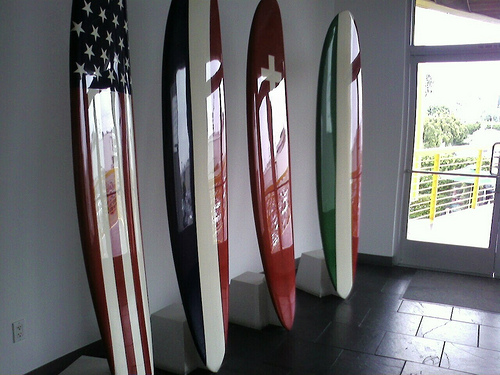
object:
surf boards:
[241, 0, 299, 333]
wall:
[2, 2, 339, 374]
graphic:
[315, 9, 366, 301]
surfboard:
[158, 1, 235, 372]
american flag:
[66, 0, 155, 374]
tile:
[351, 287, 403, 314]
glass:
[403, 41, 498, 250]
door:
[389, 53, 500, 276]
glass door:
[403, 47, 500, 245]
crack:
[420, 317, 447, 337]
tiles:
[397, 359, 480, 372]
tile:
[316, 322, 387, 354]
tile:
[437, 339, 499, 374]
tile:
[358, 307, 422, 333]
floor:
[60, 266, 497, 372]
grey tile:
[369, 332, 454, 367]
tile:
[356, 301, 418, 336]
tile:
[268, 335, 342, 370]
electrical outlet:
[11, 316, 26, 343]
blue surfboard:
[158, 0, 207, 374]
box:
[223, 269, 295, 333]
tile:
[361, 273, 412, 299]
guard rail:
[406, 142, 498, 222]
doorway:
[389, 49, 499, 279]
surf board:
[64, 0, 156, 375]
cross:
[256, 56, 286, 97]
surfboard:
[313, 5, 362, 300]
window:
[408, 0, 500, 48]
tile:
[473, 322, 498, 349]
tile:
[412, 313, 480, 350]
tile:
[447, 306, 497, 328]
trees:
[421, 93, 491, 143]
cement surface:
[410, 204, 491, 248]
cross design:
[257, 51, 288, 97]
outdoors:
[404, 60, 500, 253]